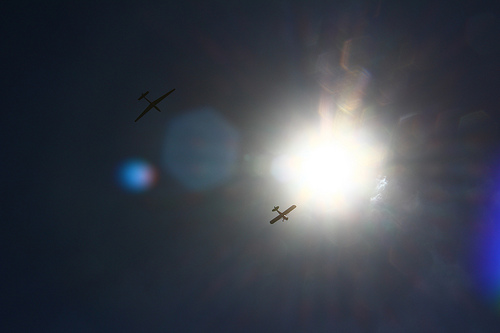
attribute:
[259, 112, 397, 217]
sun — bright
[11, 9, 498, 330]
sky — outdoors, clear, deep blue, blue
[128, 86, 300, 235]
airplanes — flying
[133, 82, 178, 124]
airplane — flying, black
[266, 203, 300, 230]
airplane — flying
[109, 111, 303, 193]
sun spots — enormous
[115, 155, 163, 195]
spot — blue, bright, rainbow colored, octagonal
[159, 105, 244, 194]
spot — enormous